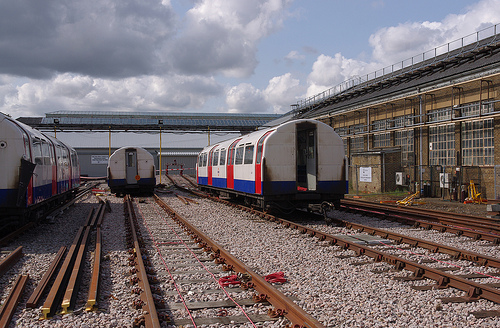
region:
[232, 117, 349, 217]
a white red and blue train car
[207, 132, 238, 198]
a white red and blue train car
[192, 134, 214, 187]
a white red and blue train car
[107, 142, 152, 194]
a white red and blue train car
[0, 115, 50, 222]
a white red and blue train car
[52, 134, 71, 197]
a white red and blue train car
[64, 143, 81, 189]
a white red and blue train car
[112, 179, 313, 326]
a set of railroad tracks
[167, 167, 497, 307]
a set of railroad tracks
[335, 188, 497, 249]
a set of railroad tracks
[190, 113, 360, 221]
A train's colors are red, white, and blue.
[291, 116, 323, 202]
A rear door on a train is open.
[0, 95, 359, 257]
Three trains are sitting on train tracks.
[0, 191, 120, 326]
Pieces of railing are sitting beside a track.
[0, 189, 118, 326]
The color of pieces of railing are brown.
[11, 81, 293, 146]
An overhead area is over some tracks.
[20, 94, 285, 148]
The color of an overhead area is gray.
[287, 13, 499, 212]
A building is beside a set of railroad tracks.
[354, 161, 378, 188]
A sign is on the outside of a building.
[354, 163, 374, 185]
The color of a sign is white with black lettering.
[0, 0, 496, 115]
the sky is cloudy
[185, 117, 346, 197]
this is a train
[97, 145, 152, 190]
this is a train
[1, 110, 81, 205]
this is a train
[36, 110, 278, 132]
this is a shade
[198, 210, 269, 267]
a rail way truck line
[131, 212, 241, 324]
a rail way truck line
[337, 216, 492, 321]
a rail way truck line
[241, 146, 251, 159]
a window on the train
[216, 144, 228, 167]
a window on the train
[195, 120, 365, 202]
train is blue red and white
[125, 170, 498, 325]
train is on tracks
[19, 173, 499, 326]
gravel is between tracks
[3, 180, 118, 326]
track parts between tracks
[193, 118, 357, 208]
train car carries people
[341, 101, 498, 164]
windows on bulding wall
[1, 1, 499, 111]
sky is blue and cloudy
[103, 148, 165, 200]
train car off tracks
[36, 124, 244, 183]
fence behind trains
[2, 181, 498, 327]
there are three sets of tracks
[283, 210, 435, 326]
tracks for the train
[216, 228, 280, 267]
gravel between the tracks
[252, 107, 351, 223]
back of the train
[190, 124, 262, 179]
windows on the side of train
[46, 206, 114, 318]
extra rods for the train tracks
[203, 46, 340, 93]
clouds in the sky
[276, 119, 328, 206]
open door of train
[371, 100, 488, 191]
windows of the building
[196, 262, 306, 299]
trash on the train tracks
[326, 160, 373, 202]
sign on the wall